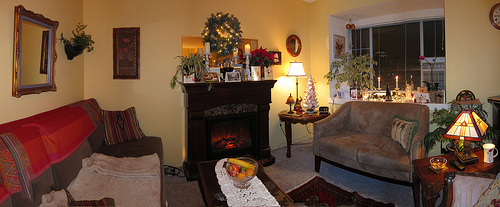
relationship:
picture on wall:
[107, 26, 144, 86] [83, 2, 311, 150]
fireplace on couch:
[178, 73, 278, 175] [0, 98, 164, 207]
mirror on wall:
[11, 5, 58, 99] [1, 0, 499, 171]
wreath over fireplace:
[198, 13, 250, 61] [178, 73, 278, 175]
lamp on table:
[283, 58, 311, 82] [280, 102, 327, 159]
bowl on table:
[220, 152, 262, 191] [195, 154, 295, 206]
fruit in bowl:
[226, 158, 256, 181] [220, 152, 262, 191]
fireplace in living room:
[181, 80, 276, 176] [23, 17, 499, 205]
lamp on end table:
[286, 60, 308, 111] [408, 150, 495, 203]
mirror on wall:
[11, 5, 58, 99] [144, 82, 171, 127]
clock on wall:
[486, 3, 499, 26] [452, 2, 499, 89]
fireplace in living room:
[188, 71, 293, 178] [7, 6, 481, 191]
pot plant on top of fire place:
[177, 42, 223, 90] [202, 108, 264, 159]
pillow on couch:
[97, 103, 148, 147] [0, 96, 164, 203]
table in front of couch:
[181, 150, 303, 204] [0, 96, 164, 203]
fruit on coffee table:
[221, 155, 258, 180] [193, 152, 303, 205]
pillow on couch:
[375, 106, 420, 153] [313, 101, 429, 205]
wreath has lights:
[201, 13, 243, 52] [228, 32, 240, 45]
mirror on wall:
[11, 5, 58, 99] [0, 0, 84, 130]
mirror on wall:
[18, 23, 53, 86] [0, 0, 84, 130]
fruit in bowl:
[226, 158, 256, 181] [226, 157, 259, 189]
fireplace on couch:
[178, 73, 278, 175] [0, 96, 164, 203]